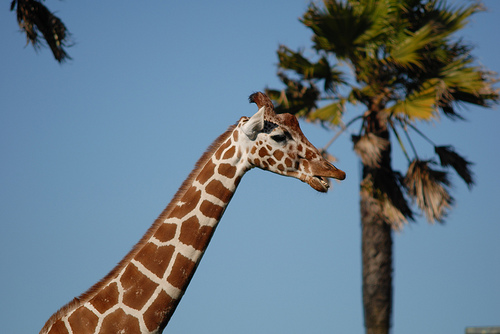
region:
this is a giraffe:
[15, 62, 350, 326]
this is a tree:
[254, 3, 482, 328]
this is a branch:
[393, 52, 448, 119]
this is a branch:
[259, 43, 364, 150]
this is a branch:
[388, 11, 484, 150]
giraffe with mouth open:
[235, 95, 347, 193]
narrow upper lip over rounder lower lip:
[291, 142, 346, 193]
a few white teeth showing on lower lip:
[301, 175, 331, 193]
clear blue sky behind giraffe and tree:
[12, 13, 489, 323]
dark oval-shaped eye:
[269, 130, 286, 145]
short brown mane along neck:
[32, 122, 234, 329]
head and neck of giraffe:
[40, 104, 359, 332]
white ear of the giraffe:
[239, 107, 270, 140]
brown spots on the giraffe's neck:
[58, 127, 240, 332]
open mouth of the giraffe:
[309, 164, 343, 191]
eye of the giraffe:
[269, 127, 286, 144]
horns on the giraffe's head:
[250, 83, 271, 118]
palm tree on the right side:
[258, 27, 487, 332]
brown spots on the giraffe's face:
[244, 145, 318, 178]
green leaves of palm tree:
[266, 1, 498, 332]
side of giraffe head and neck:
[43, 87, 345, 330]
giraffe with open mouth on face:
[45, 89, 345, 331]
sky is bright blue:
[1, 1, 498, 333]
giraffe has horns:
[36, 89, 347, 332]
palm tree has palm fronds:
[262, 1, 499, 333]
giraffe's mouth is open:
[35, 88, 347, 332]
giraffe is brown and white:
[37, 91, 346, 332]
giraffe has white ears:
[41, 91, 347, 331]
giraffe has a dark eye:
[34, 91, 346, 332]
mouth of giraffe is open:
[310, 162, 341, 190]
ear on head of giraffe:
[242, 102, 265, 134]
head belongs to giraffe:
[231, 90, 342, 195]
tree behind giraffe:
[255, 0, 498, 330]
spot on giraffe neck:
[203, 177, 233, 202]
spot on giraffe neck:
[180, 216, 211, 247]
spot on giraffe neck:
[167, 250, 195, 288]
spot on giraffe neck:
[132, 241, 173, 276]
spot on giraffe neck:
[78, 278, 118, 311]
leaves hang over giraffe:
[8, 0, 75, 68]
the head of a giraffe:
[215, 83, 347, 198]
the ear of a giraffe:
[235, 108, 275, 143]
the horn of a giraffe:
[240, 93, 291, 123]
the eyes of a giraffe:
[258, 121, 306, 153]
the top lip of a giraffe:
[311, 158, 358, 186]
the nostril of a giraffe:
[315, 159, 335, 174]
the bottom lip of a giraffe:
[307, 175, 328, 200]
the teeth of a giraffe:
[315, 173, 330, 190]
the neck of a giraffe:
[118, 155, 249, 312]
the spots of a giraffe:
[160, 239, 198, 286]